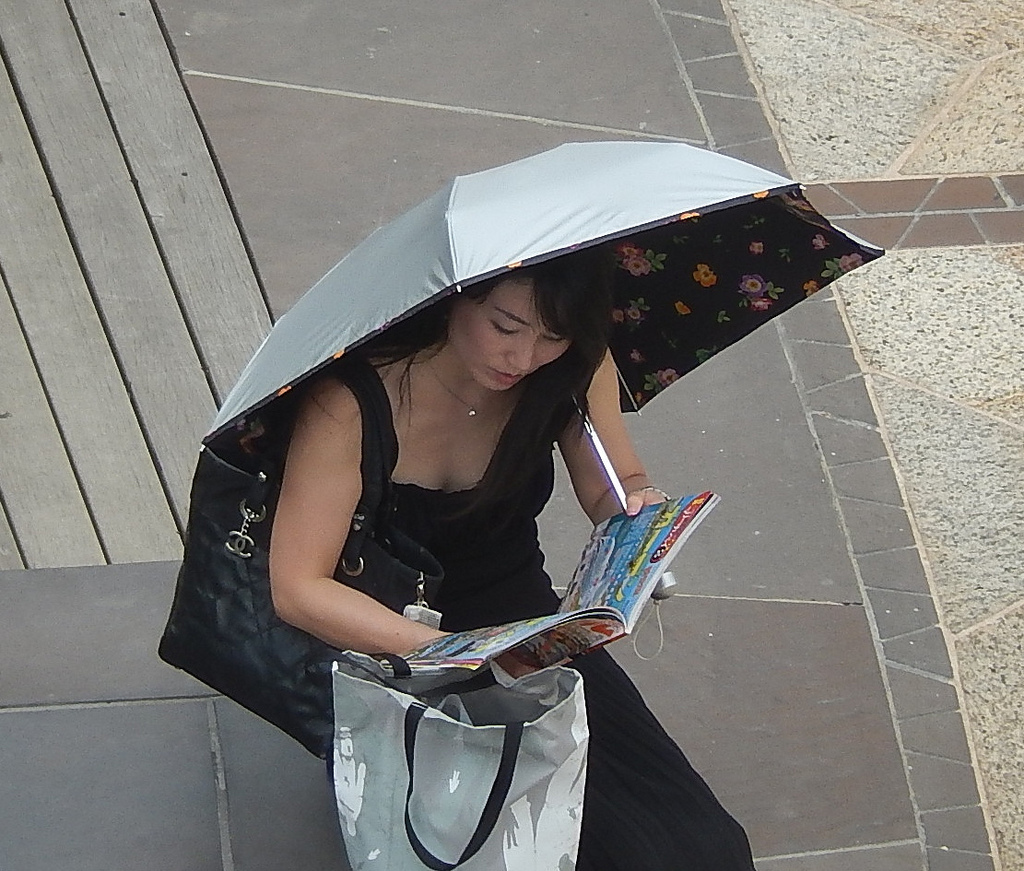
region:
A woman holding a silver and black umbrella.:
[155, 137, 889, 868]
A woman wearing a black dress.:
[152, 138, 889, 866]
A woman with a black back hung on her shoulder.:
[152, 136, 886, 865]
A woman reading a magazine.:
[152, 136, 887, 865]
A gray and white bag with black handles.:
[326, 646, 589, 866]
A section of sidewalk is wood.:
[0, 0, 272, 571]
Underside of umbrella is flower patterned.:
[198, 125, 887, 656]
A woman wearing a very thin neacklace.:
[150, 136, 882, 865]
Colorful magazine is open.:
[374, 480, 720, 703]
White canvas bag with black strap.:
[329, 650, 587, 867]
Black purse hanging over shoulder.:
[164, 349, 446, 771]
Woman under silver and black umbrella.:
[184, 138, 873, 448]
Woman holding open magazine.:
[268, 251, 753, 852]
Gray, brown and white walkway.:
[721, 6, 1016, 858]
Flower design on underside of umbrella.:
[692, 258, 721, 296]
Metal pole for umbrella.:
[584, 415, 636, 530]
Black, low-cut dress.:
[284, 357, 753, 867]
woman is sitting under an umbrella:
[153, 128, 903, 868]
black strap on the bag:
[377, 690, 536, 868]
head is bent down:
[399, 245, 622, 422]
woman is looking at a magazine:
[248, 193, 805, 868]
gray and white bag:
[317, 645, 611, 868]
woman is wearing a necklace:
[437, 361, 510, 434]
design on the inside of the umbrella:
[564, 183, 913, 441]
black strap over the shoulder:
[340, 352, 414, 495]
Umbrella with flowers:
[203, 142, 884, 485]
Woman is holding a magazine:
[267, 240, 717, 869]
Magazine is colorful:
[381, 490, 720, 687]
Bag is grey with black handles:
[330, 651, 591, 868]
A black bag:
[157, 353, 443, 758]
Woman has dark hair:
[270, 246, 670, 869]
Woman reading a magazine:
[270, 246, 752, 869]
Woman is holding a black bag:
[160, 241, 753, 868]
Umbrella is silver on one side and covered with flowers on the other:
[204, 139, 884, 479]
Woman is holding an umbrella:
[179, 138, 884, 869]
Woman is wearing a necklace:
[413, 344, 515, 420]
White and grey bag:
[326, 648, 596, 868]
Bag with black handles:
[329, 645, 589, 868]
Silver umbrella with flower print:
[203, 141, 884, 502]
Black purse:
[155, 348, 444, 760]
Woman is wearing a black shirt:
[367, 342, 592, 614]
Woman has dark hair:
[371, 241, 624, 426]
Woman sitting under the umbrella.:
[204, 139, 887, 446]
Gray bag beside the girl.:
[324, 642, 591, 864]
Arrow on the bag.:
[444, 765, 464, 800]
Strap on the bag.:
[400, 699, 528, 867]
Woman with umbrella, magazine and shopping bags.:
[116, 123, 888, 869]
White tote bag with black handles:
[335, 648, 624, 868]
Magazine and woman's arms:
[388, 490, 722, 680]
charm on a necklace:
[442, 382, 500, 428]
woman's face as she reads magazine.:
[462, 279, 592, 415]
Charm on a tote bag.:
[211, 499, 268, 567]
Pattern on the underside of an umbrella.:
[615, 231, 784, 312]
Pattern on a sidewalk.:
[29, 141, 195, 456]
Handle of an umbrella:
[578, 407, 636, 503]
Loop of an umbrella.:
[626, 574, 683, 667]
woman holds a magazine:
[148, 121, 906, 868]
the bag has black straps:
[318, 647, 608, 867]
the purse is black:
[142, 356, 459, 769]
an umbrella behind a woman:
[189, 109, 906, 553]